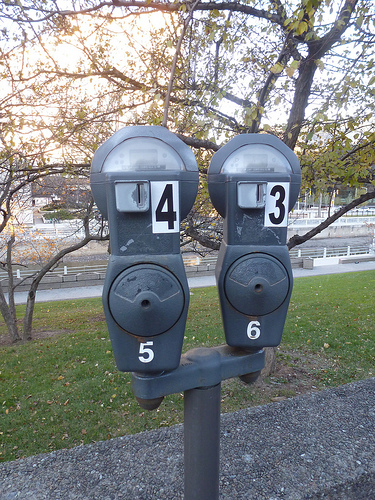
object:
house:
[33, 195, 53, 207]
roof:
[31, 175, 86, 195]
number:
[246, 318, 263, 342]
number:
[269, 181, 286, 225]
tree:
[0, 155, 108, 343]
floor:
[0, 388, 375, 500]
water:
[19, 214, 365, 256]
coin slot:
[135, 181, 143, 204]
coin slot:
[255, 182, 260, 202]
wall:
[2, 376, 373, 498]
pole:
[182, 380, 219, 499]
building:
[0, 171, 34, 226]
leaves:
[44, 237, 57, 250]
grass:
[0, 268, 373, 450]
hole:
[137, 296, 153, 312]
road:
[1, 283, 102, 305]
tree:
[95, 1, 374, 253]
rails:
[0, 265, 101, 287]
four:
[156, 183, 176, 229]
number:
[135, 339, 156, 364]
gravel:
[0, 388, 373, 497]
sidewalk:
[1, 352, 373, 498]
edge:
[180, 366, 222, 397]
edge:
[182, 357, 222, 382]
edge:
[315, 477, 371, 499]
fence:
[0, 243, 375, 291]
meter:
[206, 134, 300, 348]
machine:
[89, 125, 198, 372]